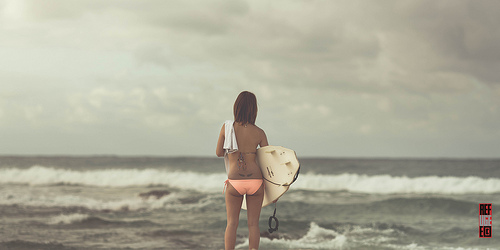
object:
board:
[241, 145, 301, 210]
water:
[0, 153, 499, 250]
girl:
[215, 91, 270, 250]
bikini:
[223, 152, 263, 196]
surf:
[232, 212, 424, 248]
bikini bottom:
[223, 178, 264, 195]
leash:
[268, 202, 279, 233]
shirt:
[223, 121, 239, 154]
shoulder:
[220, 121, 237, 130]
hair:
[233, 91, 257, 128]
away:
[0, 0, 500, 250]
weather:
[5, 0, 494, 240]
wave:
[3, 158, 500, 223]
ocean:
[2, 154, 499, 247]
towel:
[223, 120, 238, 153]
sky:
[5, 5, 494, 155]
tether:
[268, 202, 279, 233]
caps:
[3, 158, 499, 191]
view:
[215, 90, 300, 250]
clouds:
[7, 5, 500, 146]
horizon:
[0, 151, 500, 163]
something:
[223, 120, 238, 154]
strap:
[268, 202, 279, 233]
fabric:
[223, 120, 239, 154]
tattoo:
[238, 173, 253, 177]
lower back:
[228, 170, 262, 179]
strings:
[237, 152, 248, 170]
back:
[227, 123, 262, 178]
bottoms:
[222, 178, 264, 195]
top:
[226, 151, 258, 170]